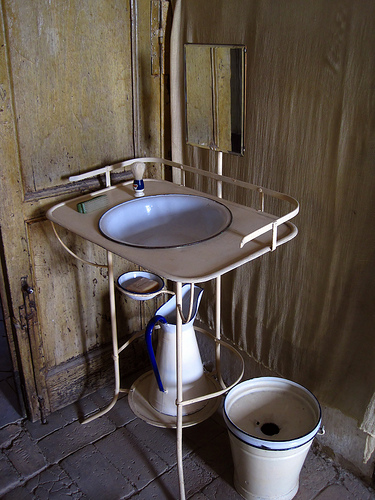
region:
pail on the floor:
[209, 372, 331, 494]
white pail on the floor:
[212, 376, 329, 496]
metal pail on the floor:
[211, 372, 326, 491]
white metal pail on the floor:
[218, 375, 330, 492]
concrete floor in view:
[23, 424, 157, 486]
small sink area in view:
[41, 165, 284, 328]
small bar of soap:
[120, 271, 165, 301]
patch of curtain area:
[293, 229, 370, 348]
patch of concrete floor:
[8, 424, 147, 489]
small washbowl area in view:
[60, 197, 295, 298]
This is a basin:
[222, 359, 336, 494]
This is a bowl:
[82, 183, 230, 271]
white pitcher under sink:
[142, 294, 211, 412]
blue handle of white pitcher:
[139, 308, 169, 388]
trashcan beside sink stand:
[229, 377, 318, 498]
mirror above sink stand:
[182, 46, 243, 156]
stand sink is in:
[50, 151, 297, 493]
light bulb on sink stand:
[127, 159, 146, 183]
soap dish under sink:
[116, 266, 159, 299]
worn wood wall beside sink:
[2, 5, 154, 418]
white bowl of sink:
[104, 191, 229, 252]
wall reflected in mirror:
[189, 47, 235, 143]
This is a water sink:
[22, 146, 326, 298]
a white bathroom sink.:
[87, 191, 235, 258]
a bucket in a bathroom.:
[219, 368, 328, 498]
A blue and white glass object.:
[131, 293, 201, 414]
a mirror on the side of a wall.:
[178, 32, 253, 160]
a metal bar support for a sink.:
[69, 385, 120, 430]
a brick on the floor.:
[56, 422, 170, 497]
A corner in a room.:
[152, 0, 188, 182]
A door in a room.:
[0, 0, 161, 422]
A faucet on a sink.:
[129, 170, 154, 202]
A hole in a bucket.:
[256, 405, 292, 452]